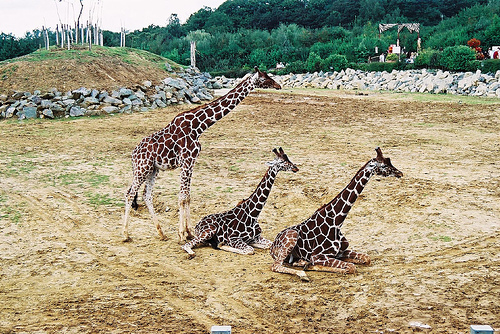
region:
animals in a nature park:
[15, 7, 480, 317]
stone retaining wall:
[330, 65, 462, 90]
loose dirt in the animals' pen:
[275, 282, 435, 327]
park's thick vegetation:
[239, 0, 341, 58]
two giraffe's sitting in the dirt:
[201, 135, 406, 280]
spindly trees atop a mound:
[15, 1, 150, 81]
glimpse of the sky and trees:
[125, 0, 175, 45]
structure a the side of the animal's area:
[360, 11, 432, 66]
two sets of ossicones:
[261, 140, 386, 160]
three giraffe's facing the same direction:
[125, 56, 408, 283]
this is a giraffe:
[118, 35, 280, 250]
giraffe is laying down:
[268, 130, 443, 295]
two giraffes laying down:
[146, 125, 431, 298]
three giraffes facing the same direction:
[115, 27, 449, 321]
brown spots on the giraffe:
[145, 110, 200, 166]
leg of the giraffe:
[268, 256, 319, 292]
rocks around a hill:
[5, 0, 215, 123]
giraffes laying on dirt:
[110, 48, 424, 332]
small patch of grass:
[25, 140, 113, 210]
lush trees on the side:
[199, 7, 471, 86]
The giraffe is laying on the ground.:
[268, 132, 405, 282]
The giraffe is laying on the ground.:
[181, 137, 299, 257]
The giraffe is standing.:
[117, 60, 284, 247]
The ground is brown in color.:
[30, 256, 165, 322]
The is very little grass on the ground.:
[18, 149, 108, 201]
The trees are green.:
[237, 7, 344, 53]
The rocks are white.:
[352, 71, 448, 94]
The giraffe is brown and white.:
[274, 144, 404, 275]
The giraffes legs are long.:
[180, 162, 199, 236]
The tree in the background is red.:
[466, 35, 488, 60]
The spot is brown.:
[313, 210, 325, 229]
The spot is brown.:
[318, 205, 329, 220]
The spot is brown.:
[331, 195, 348, 217]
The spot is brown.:
[313, 232, 327, 246]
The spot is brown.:
[299, 236, 313, 253]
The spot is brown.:
[248, 208, 261, 222]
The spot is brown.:
[254, 198, 264, 211]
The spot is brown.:
[261, 184, 271, 199]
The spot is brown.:
[179, 118, 193, 135]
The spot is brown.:
[204, 116, 215, 127]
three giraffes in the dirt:
[121, 67, 405, 277]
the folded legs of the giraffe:
[306, 247, 368, 275]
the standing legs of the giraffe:
[122, 172, 206, 246]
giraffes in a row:
[123, 65, 403, 277]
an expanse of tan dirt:
[3, 95, 498, 332]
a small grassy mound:
[0, 35, 213, 117]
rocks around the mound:
[0, 67, 215, 126]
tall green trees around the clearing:
[3, 0, 492, 74]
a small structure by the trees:
[370, 21, 423, 66]